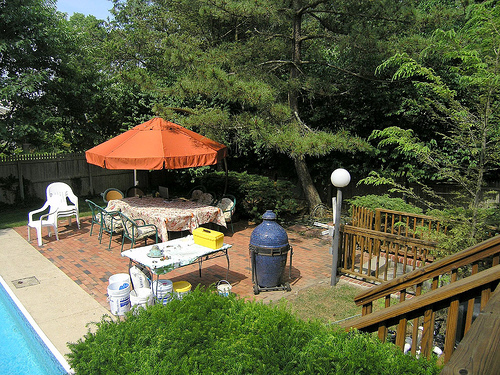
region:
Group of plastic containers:
[107, 261, 192, 317]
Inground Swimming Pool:
[0, 226, 120, 373]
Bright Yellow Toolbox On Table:
[190, 224, 227, 249]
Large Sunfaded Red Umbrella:
[82, 112, 224, 214]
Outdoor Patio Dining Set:
[87, 181, 238, 248]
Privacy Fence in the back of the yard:
[2, 146, 152, 226]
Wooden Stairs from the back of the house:
[340, 223, 497, 363]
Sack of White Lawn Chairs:
[43, 180, 83, 235]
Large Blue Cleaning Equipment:
[248, 209, 295, 296]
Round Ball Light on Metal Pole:
[326, 165, 351, 285]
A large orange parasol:
[83, 110, 230, 205]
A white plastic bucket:
[102, 280, 128, 311]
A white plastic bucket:
[150, 276, 171, 297]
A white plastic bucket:
[215, 280, 231, 290]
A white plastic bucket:
[127, 288, 152, 310]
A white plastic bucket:
[108, 270, 130, 283]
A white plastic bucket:
[126, 263, 151, 289]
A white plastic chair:
[23, 193, 63, 246]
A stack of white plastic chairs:
[45, 178, 82, 226]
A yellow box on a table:
[193, 224, 222, 247]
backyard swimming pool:
[3, 282, 76, 372]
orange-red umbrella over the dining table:
[83, 110, 225, 183]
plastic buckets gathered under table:
[101, 264, 204, 318]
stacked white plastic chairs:
[28, 171, 80, 248]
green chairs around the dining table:
[88, 181, 238, 251]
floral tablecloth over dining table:
[104, 190, 227, 237]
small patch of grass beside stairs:
[259, 287, 480, 373]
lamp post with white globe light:
[321, 157, 358, 297]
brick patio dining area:
[16, 207, 386, 302]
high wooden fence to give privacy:
[0, 133, 158, 219]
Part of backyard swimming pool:
[0, 266, 77, 373]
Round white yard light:
[324, 166, 353, 191]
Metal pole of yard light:
[318, 191, 345, 285]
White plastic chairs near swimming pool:
[22, 179, 82, 246]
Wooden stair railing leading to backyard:
[319, 236, 499, 367]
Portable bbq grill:
[244, 208, 296, 298]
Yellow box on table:
[188, 225, 228, 255]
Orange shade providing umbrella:
[77, 112, 233, 177]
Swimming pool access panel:
[7, 274, 43, 294]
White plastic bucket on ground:
[99, 280, 131, 315]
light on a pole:
[317, 163, 357, 284]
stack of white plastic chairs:
[44, 178, 83, 231]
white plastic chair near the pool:
[23, 193, 62, 253]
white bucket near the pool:
[102, 277, 129, 319]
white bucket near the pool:
[127, 286, 155, 312]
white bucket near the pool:
[152, 276, 173, 304]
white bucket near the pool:
[103, 269, 130, 287]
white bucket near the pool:
[215, 280, 234, 297]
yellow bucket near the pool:
[169, 278, 197, 300]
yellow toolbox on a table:
[187, 224, 225, 249]